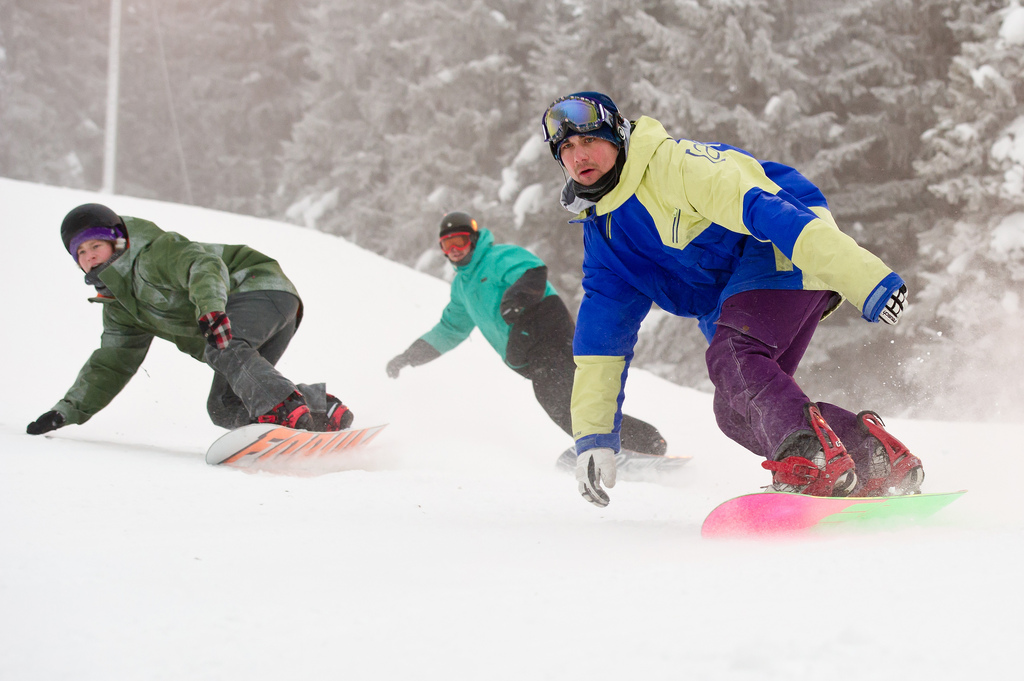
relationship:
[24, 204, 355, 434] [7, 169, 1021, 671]
snowboarder on snow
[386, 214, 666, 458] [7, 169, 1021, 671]
person on snow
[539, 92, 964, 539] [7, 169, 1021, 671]
skier on snow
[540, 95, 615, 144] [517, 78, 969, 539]
goggles on skier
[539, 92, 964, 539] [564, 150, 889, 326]
skier wearing a jacket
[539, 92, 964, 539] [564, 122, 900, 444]
skier wearing jacket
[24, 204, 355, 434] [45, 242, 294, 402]
snowboarder wearing jacket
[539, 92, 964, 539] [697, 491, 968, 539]
skier riding snowboard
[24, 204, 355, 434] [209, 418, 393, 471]
snowboarder riding snowboard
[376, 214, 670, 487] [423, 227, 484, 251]
person wearing goggles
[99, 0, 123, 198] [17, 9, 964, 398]
pole in front of trees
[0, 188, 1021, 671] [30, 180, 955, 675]
snow covering ground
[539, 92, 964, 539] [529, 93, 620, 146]
skier with goggles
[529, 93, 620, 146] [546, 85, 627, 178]
goggles on head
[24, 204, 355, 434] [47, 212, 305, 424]
snowboarder wearing coat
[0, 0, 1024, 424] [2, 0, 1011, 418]
evergreens covered with snow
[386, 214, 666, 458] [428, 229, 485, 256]
person wearing goggles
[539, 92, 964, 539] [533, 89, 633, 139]
skier wearing goggles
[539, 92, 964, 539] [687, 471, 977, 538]
skier has snowboard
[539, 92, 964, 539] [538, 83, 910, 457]
skier wearing jacket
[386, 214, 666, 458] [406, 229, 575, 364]
person wearing jacket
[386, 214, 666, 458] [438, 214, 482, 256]
person wearing goggles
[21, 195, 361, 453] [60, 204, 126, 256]
snowboarder wearing helmet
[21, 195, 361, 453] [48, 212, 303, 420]
snowboarder wearing jacket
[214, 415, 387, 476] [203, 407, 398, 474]
letters on snowboard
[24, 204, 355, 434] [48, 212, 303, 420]
snowboarder wearing jacket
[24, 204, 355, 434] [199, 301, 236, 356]
snowboarder wearing glove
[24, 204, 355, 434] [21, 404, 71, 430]
snowboarder wearing glove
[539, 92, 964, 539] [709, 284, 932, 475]
skier wearing ski pants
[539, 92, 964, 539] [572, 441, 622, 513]
skier wearing glove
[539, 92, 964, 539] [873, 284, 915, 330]
skier wearing glove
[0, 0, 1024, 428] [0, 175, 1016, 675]
pine trees on slope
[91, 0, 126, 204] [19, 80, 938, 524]
pole near snowboarders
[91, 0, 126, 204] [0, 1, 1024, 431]
pole near trees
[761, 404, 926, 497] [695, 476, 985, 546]
snowboard on snowboard